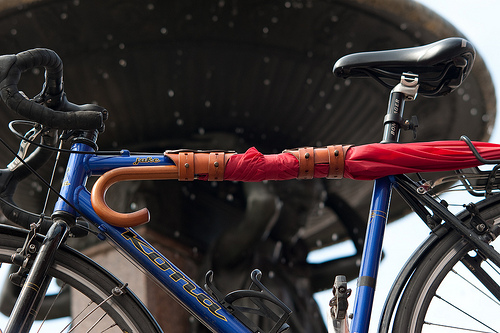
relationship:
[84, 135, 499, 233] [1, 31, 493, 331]
umbrella strapped to bicycle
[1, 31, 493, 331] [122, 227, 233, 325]
bicycle has black writing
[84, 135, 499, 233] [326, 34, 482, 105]
umbrella strapped under seat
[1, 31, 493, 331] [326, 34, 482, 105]
bike has black seat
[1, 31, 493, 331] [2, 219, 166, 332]
bike has a tire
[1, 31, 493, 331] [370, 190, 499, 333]
bike has a tire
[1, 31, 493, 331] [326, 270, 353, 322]
bike has a pedal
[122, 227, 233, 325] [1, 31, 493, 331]
logo on bike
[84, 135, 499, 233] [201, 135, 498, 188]
umbrella color red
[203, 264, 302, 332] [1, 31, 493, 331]
holder on a bike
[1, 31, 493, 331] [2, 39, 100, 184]
bike has handle bars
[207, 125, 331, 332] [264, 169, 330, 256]
statue has a head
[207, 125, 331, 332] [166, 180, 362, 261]
statue in background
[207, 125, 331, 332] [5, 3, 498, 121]
statue holding pillar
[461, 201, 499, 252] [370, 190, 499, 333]
brakes on tire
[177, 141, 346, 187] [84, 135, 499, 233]
strap holding umbrella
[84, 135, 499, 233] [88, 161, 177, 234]
umbrella has a handle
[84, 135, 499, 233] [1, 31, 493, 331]
umbrella attached to bike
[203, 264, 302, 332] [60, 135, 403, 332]
holder on frame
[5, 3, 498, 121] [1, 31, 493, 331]
structure behind bike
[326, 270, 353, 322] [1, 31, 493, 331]
pedal of a bike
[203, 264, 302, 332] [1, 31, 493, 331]
holder on bike